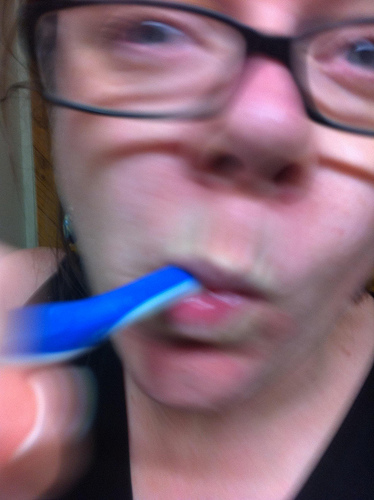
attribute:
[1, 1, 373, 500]
person — brushing, blurry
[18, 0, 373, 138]
glasses — rectangular, black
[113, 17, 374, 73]
eyes — small, light color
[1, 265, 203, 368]
toothbrush — blue, blu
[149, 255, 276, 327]
mouth — small, cream colored, pursed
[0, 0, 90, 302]
hair — black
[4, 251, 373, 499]
top — black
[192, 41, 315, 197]
nose — red, clean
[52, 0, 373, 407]
face — red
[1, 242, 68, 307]
shoulder — bare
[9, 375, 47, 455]
nail — white